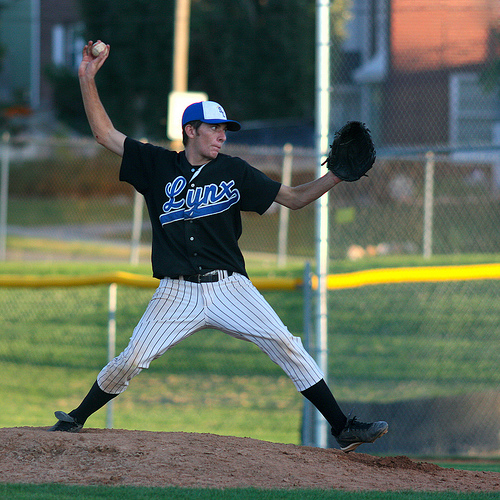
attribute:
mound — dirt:
[2, 422, 498, 494]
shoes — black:
[34, 387, 428, 466]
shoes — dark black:
[335, 420, 387, 452]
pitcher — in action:
[48, 36, 390, 456]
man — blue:
[46, 35, 389, 454]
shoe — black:
[330, 414, 389, 454]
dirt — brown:
[0, 420, 498, 490]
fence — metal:
[320, 4, 488, 440]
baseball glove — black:
[324, 118, 378, 185]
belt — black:
[163, 267, 233, 283]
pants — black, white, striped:
[91, 256, 423, 376]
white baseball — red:
[51, 21, 121, 62]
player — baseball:
[38, 20, 388, 447]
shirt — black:
[113, 131, 278, 278]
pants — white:
[92, 273, 326, 402]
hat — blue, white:
[175, 93, 238, 130]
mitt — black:
[318, 113, 385, 192]